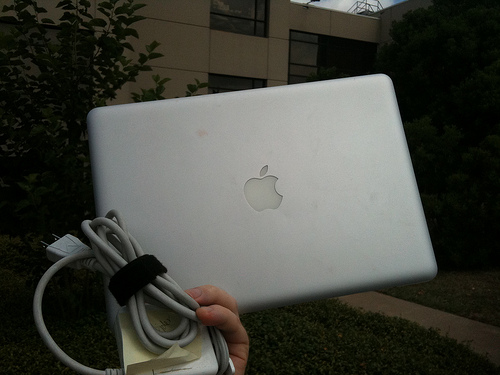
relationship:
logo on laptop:
[244, 165, 283, 213] [86, 73, 438, 311]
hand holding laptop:
[184, 286, 252, 374] [86, 73, 438, 311]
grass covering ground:
[0, 297, 492, 374] [0, 212, 498, 374]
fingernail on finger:
[198, 299, 211, 310] [194, 302, 248, 359]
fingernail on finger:
[185, 283, 204, 299] [185, 284, 238, 313]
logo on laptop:
[244, 159, 282, 211] [86, 73, 438, 311]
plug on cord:
[40, 225, 92, 263] [26, 206, 230, 374]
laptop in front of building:
[86, 73, 438, 311] [2, 0, 390, 109]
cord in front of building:
[26, 206, 230, 374] [2, 0, 390, 109]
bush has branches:
[0, 0, 229, 326] [0, 0, 215, 126]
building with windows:
[44, 49, 453, 133] [224, 112, 274, 158]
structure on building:
[345, 55, 383, 72] [34, 99, 497, 235]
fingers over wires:
[169, 263, 260, 363] [28, 208, 206, 375]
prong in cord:
[38, 224, 70, 251] [31, 212, 241, 369]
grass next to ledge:
[0, 234, 492, 373] [315, 268, 491, 367]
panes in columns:
[287, 50, 292, 79] [172, 100, 174, 104]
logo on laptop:
[244, 165, 283, 213] [64, 113, 446, 373]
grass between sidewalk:
[0, 234, 492, 373] [343, 251, 498, 357]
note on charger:
[117, 303, 207, 371] [28, 222, 97, 266]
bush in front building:
[243, 279, 498, 375] [20, 103, 480, 199]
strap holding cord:
[104, 238, 168, 297] [54, 216, 238, 375]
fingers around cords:
[178, 270, 272, 371] [35, 210, 255, 367]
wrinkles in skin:
[227, 334, 249, 361] [215, 297, 249, 367]